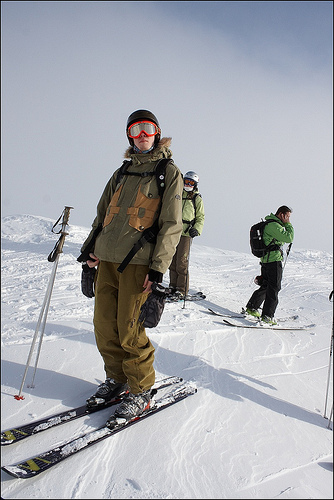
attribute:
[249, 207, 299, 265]
jacket — green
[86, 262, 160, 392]
jeans — green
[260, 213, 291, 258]
jacket — heavy, green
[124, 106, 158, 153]
helmet — black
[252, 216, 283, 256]
backpack — large, black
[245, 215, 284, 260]
backpack — black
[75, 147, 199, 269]
jacket — heavy, olive green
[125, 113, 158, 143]
eyewear — red, protective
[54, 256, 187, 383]
pants — khaki 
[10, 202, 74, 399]
poles — metal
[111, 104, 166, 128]
helmet — black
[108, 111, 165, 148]
goggles — red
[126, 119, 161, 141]
goggles — red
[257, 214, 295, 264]
coat — green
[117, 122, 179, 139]
goggles — red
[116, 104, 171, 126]
helmet — black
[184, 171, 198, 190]
helmet — silver